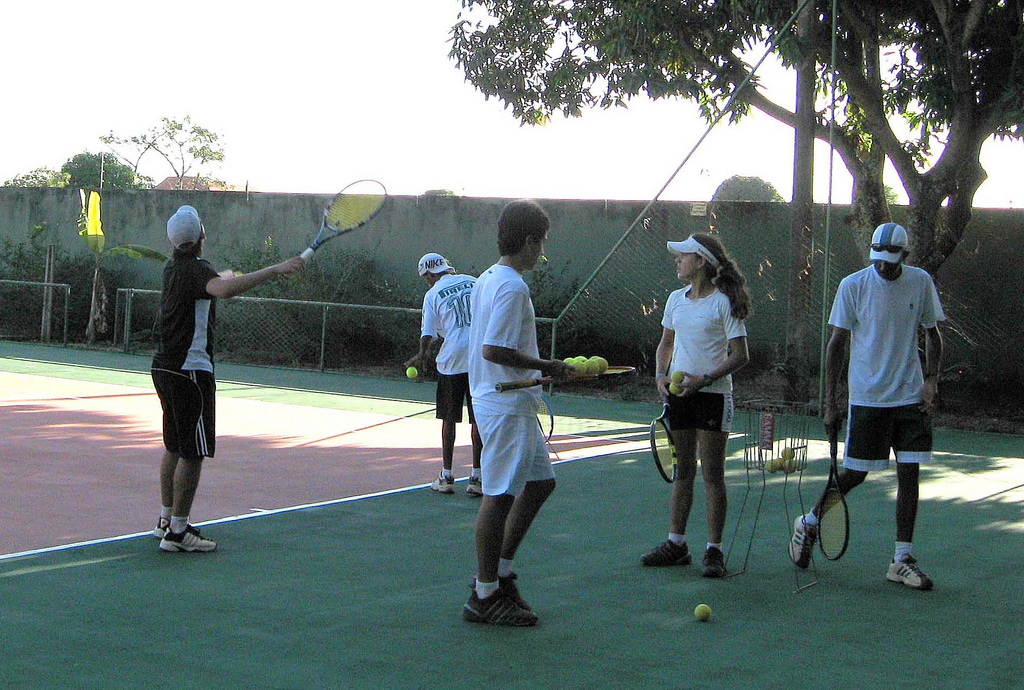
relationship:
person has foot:
[788, 214, 961, 601] [886, 564, 934, 588]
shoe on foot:
[882, 557, 935, 599] [886, 564, 934, 588]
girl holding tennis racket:
[626, 227, 758, 586] [640, 400, 684, 489]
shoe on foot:
[140, 515, 193, 559] [144, 510, 192, 571]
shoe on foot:
[466, 573, 542, 636] [461, 569, 542, 632]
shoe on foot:
[494, 567, 534, 613] [487, 573, 546, 626]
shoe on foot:
[705, 536, 736, 582] [690, 525, 742, 584]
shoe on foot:
[165, 528, 205, 554] [156, 515, 221, 554]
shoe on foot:
[439, 474, 455, 488] [457, 582, 540, 621]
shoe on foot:
[469, 480, 485, 500] [429, 463, 455, 494]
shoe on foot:
[462, 586, 541, 626] [640, 532, 695, 582]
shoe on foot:
[158, 527, 219, 554] [154, 500, 226, 567]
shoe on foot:
[430, 469, 455, 493] [426, 463, 457, 505]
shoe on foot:
[466, 475, 483, 496] [454, 461, 496, 500]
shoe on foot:
[462, 586, 541, 626] [463, 579, 535, 632]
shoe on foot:
[645, 541, 685, 565] [638, 521, 706, 576]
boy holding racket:
[145, 199, 245, 584] [305, 160, 392, 271]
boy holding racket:
[450, 195, 589, 632] [500, 361, 641, 390]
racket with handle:
[307, 176, 392, 261] [271, 238, 323, 282]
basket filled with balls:
[744, 396, 816, 475] [763, 439, 800, 478]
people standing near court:
[152, 180, 958, 636] [14, 353, 1011, 682]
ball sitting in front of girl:
[690, 595, 717, 628] [636, 231, 753, 580]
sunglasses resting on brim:
[863, 232, 905, 261] [867, 240, 904, 271]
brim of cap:
[867, 240, 904, 271] [870, 222, 909, 266]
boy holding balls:
[460, 199, 580, 630] [562, 351, 608, 373]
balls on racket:
[562, 351, 608, 373] [498, 366, 637, 390]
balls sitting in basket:
[761, 439, 809, 474] [722, 396, 815, 481]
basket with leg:
[722, 396, 815, 481] [785, 487, 825, 565]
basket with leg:
[722, 396, 815, 481] [725, 456, 775, 578]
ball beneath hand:
[403, 361, 419, 379] [405, 350, 432, 372]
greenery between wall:
[68, 253, 1011, 413] [3, 173, 1008, 422]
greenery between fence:
[68, 253, 1011, 413] [24, 269, 589, 384]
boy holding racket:
[148, 204, 309, 553] [301, 178, 388, 262]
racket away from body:
[301, 178, 388, 262] [163, 260, 218, 444]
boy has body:
[148, 204, 309, 553] [163, 260, 218, 444]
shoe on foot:
[462, 586, 541, 626] [467, 573, 534, 638]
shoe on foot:
[640, 537, 694, 566] [640, 530, 692, 572]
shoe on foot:
[701, 545, 726, 577] [696, 538, 735, 580]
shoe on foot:
[798, 519, 807, 561] [779, 493, 827, 574]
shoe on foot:
[885, 554, 934, 589] [880, 534, 930, 589]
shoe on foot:
[701, 545, 726, 577] [779, 502, 819, 572]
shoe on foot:
[640, 537, 694, 566] [686, 539, 736, 587]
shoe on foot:
[645, 541, 685, 565] [636, 532, 695, 576]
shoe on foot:
[462, 586, 541, 626] [463, 562, 543, 630]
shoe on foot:
[158, 527, 219, 554] [169, 521, 196, 550]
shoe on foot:
[462, 586, 541, 626] [459, 564, 539, 632]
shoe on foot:
[640, 537, 694, 566] [640, 525, 686, 577]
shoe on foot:
[701, 545, 726, 577] [696, 530, 736, 578]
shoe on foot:
[788, 512, 820, 569] [791, 506, 828, 563]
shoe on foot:
[885, 554, 934, 589] [876, 530, 954, 610]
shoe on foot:
[788, 512, 820, 569] [787, 502, 829, 582]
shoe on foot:
[701, 545, 726, 577] [686, 538, 730, 593]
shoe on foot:
[640, 537, 694, 566] [638, 534, 695, 571]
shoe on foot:
[462, 586, 541, 626] [457, 577, 557, 630]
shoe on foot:
[151, 516, 200, 539] [152, 519, 230, 558]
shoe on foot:
[462, 586, 541, 626] [456, 569, 545, 639]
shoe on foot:
[640, 537, 694, 566] [640, 521, 690, 578]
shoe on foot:
[701, 545, 726, 577] [698, 528, 742, 583]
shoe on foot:
[788, 512, 820, 569] [783, 506, 831, 573]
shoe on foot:
[885, 554, 934, 589] [876, 539, 935, 591]